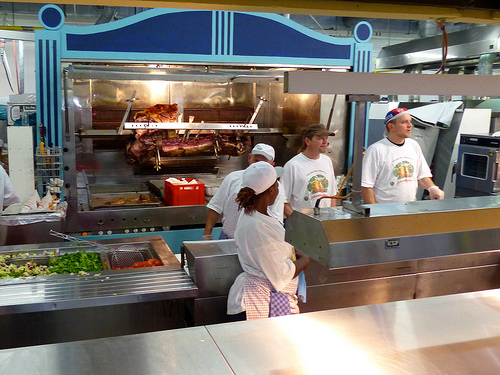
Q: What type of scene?
A: Indoor.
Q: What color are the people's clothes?
A: White.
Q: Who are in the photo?
A: People.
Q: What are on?
A: Lights.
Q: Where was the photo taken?
A: Kitchen.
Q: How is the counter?
A: Shiny.